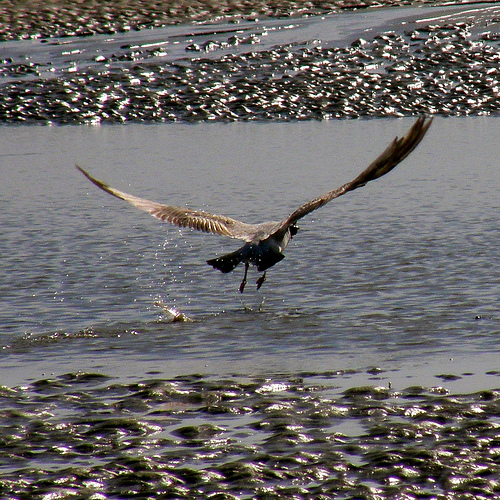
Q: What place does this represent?
A: It represents the shore.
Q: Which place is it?
A: It is a shore.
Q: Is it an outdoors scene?
A: Yes, it is outdoors.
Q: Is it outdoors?
A: Yes, it is outdoors.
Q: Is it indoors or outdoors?
A: It is outdoors.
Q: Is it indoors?
A: No, it is outdoors.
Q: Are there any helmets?
A: No, there are no helmets.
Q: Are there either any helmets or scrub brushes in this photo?
A: No, there are no helmets or scrub brushes.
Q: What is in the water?
A: The fish is in the water.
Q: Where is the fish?
A: The fish is in the water.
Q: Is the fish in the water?
A: Yes, the fish is in the water.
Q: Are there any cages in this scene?
A: No, there are no cages.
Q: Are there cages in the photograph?
A: No, there are no cages.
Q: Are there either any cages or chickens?
A: No, there are no cages or chickens.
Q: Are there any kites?
A: No, there are no kites.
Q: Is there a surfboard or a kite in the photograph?
A: No, there are no kites or surfboards.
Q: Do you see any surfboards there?
A: No, there are no surfboards.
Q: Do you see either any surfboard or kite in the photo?
A: No, there are no surfboards or kites.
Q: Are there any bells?
A: No, there are no bells.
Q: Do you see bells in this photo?
A: No, there are no bells.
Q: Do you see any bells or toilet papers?
A: No, there are no bells or toilet papers.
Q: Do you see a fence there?
A: No, there are no fences.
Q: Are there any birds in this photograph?
A: Yes, there is a bird.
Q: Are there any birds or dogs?
A: Yes, there is a bird.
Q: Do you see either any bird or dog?
A: Yes, there is a bird.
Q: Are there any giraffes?
A: No, there are no giraffes.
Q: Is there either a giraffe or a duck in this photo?
A: No, there are no giraffes or ducks.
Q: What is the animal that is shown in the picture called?
A: The animal is a bird.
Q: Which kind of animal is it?
A: The animal is a bird.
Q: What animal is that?
A: This is a bird.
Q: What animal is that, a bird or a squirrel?
A: This is a bird.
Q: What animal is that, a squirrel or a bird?
A: This is a bird.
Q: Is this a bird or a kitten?
A: This is a bird.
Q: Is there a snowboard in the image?
A: No, there are no snowboards.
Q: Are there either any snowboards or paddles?
A: No, there are no snowboards or paddles.